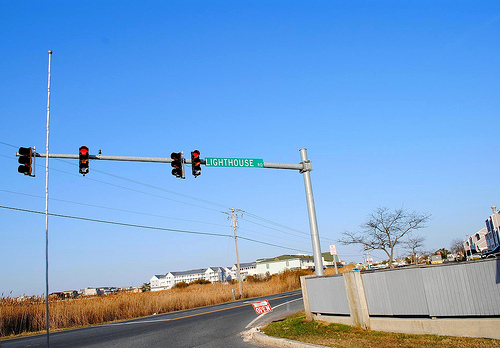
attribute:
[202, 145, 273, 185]
sign — street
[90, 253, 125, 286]
sky — clear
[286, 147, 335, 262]
pole — silver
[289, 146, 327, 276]
pole — metal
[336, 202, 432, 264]
tree — old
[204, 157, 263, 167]
sign — green